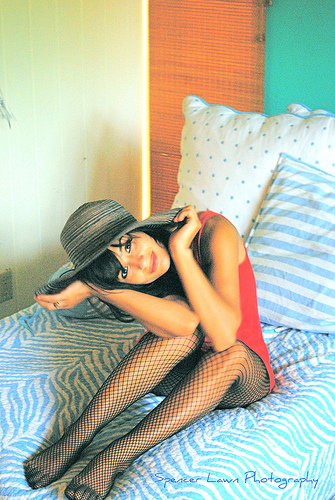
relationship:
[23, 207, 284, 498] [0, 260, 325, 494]
woman sitting on bed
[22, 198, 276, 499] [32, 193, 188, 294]
girl wearing hat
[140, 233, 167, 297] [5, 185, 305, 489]
mouth of girl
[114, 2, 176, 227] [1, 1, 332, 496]
corner of bedroom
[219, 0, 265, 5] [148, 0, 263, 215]
wood blind covering window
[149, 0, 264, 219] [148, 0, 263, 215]
blind covering window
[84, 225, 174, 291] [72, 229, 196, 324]
woman with hair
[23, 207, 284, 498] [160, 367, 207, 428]
woman wearing hose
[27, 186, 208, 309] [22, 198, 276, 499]
hat on girl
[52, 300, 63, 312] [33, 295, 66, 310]
ring on finger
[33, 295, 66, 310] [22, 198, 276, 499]
finger of girl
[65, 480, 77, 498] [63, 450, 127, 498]
toe on foot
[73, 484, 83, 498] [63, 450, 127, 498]
toe on foot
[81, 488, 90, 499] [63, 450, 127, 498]
toe on foot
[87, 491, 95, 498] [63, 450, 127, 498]
toe on foot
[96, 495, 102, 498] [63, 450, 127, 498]
toe on foot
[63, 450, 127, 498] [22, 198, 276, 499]
foot of girl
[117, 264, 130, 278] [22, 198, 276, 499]
eye of girl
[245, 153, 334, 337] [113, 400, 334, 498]
pillow on bed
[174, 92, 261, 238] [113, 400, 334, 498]
pillow on bed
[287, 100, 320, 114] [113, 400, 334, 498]
pillow on bed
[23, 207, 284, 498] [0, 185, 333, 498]
woman sitting up bed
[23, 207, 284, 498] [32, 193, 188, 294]
woman wears hat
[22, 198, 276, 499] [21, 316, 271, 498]
girl wears fishnet stockings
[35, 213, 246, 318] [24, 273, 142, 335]
girl has hand